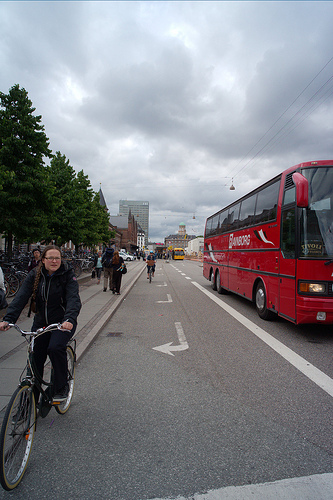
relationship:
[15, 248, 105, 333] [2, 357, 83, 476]
woman on bike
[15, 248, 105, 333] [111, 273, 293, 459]
woman on road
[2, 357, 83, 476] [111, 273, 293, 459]
bike on road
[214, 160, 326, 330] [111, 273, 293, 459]
bus on road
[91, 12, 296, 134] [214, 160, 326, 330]
sky above bus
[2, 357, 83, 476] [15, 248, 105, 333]
bike on woman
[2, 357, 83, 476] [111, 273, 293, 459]
bike in road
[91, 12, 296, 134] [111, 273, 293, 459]
sky above road